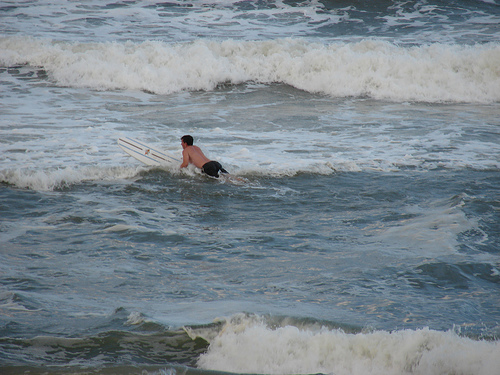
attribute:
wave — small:
[55, 21, 484, 138]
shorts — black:
[203, 156, 226, 176]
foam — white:
[9, 25, 499, 103]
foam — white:
[7, 115, 499, 197]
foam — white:
[191, 311, 495, 365]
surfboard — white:
[112, 130, 184, 167]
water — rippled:
[2, 1, 499, 373]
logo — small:
[146, 147, 151, 159]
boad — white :
[114, 138, 183, 168]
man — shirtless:
[175, 134, 230, 177]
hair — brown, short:
[175, 128, 196, 147]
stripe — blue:
[120, 144, 193, 175]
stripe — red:
[116, 136, 183, 166]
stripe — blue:
[126, 131, 179, 161]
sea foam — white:
[2, 28, 498, 105]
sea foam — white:
[194, 316, 498, 374]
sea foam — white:
[0, 129, 497, 188]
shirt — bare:
[177, 145, 218, 167]